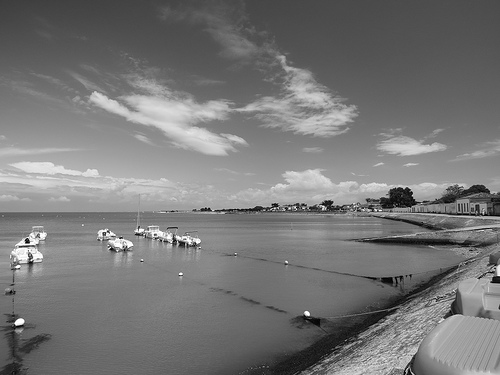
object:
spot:
[2, 285, 18, 296]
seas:
[0, 211, 471, 374]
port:
[199, 185, 499, 375]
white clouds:
[16, 55, 251, 159]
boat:
[107, 236, 134, 253]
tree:
[380, 186, 417, 208]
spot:
[316, 251, 396, 271]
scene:
[0, 0, 500, 375]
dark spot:
[0, 312, 68, 375]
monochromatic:
[358, 0, 499, 102]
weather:
[38, 34, 498, 206]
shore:
[284, 204, 494, 370]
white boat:
[11, 245, 46, 266]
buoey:
[178, 272, 184, 276]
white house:
[456, 191, 500, 216]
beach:
[164, 191, 499, 374]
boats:
[14, 225, 49, 247]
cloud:
[0, 0, 499, 212]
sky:
[0, 0, 500, 210]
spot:
[373, 271, 413, 286]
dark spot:
[206, 286, 288, 313]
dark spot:
[222, 252, 378, 279]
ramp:
[359, 212, 499, 243]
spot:
[292, 313, 322, 328]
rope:
[279, 263, 480, 373]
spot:
[209, 284, 226, 294]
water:
[0, 212, 474, 375]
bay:
[0, 212, 482, 375]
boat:
[96, 228, 115, 242]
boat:
[177, 230, 202, 249]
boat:
[142, 225, 163, 240]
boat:
[9, 244, 43, 263]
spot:
[295, 263, 310, 270]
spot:
[263, 304, 288, 316]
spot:
[238, 292, 262, 305]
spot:
[218, 249, 238, 259]